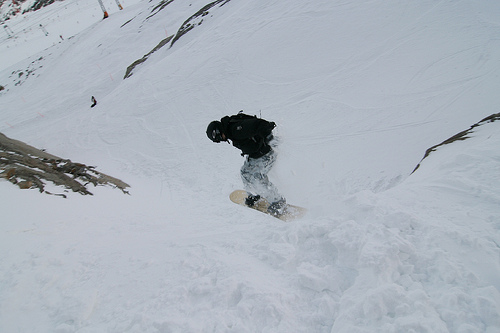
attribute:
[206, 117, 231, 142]
helmet — black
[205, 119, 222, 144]
helmet — black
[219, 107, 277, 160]
jacket — black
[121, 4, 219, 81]
rocks — distant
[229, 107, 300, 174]
jacket — black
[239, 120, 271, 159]
gear — snow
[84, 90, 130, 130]
snowboarder — distant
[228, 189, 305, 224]
snowboard — white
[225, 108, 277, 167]
jacket — black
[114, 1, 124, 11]
post — small, distant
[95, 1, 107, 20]
post — small, distant